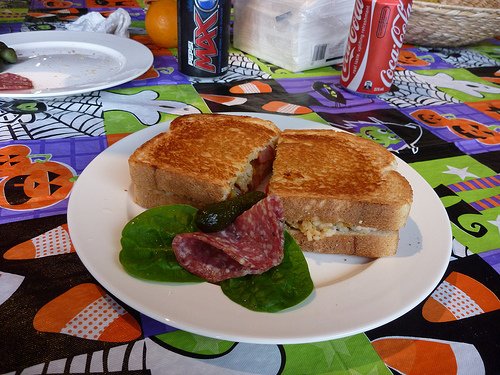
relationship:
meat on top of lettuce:
[169, 199, 286, 283] [114, 194, 317, 320]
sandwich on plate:
[120, 108, 415, 264] [64, 107, 455, 347]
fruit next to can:
[143, 1, 182, 50] [174, 1, 232, 79]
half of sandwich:
[124, 106, 279, 214] [120, 108, 415, 264]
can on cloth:
[339, 1, 411, 96] [1, 0, 500, 374]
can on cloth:
[174, 1, 232, 79] [1, 0, 500, 374]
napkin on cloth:
[63, 5, 130, 42] [1, 0, 500, 374]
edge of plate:
[141, 277, 405, 344] [64, 107, 455, 347]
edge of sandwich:
[268, 190, 411, 231] [120, 108, 415, 264]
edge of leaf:
[228, 281, 318, 314] [114, 194, 317, 320]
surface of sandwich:
[126, 112, 409, 208] [120, 108, 415, 264]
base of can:
[339, 83, 397, 97] [339, 1, 411, 96]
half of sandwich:
[262, 122, 419, 260] [120, 108, 415, 264]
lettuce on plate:
[114, 194, 317, 320] [64, 107, 455, 347]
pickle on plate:
[195, 187, 266, 232] [64, 107, 455, 347]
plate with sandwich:
[64, 107, 455, 347] [120, 108, 415, 264]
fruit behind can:
[143, 1, 182, 50] [174, 1, 232, 79]